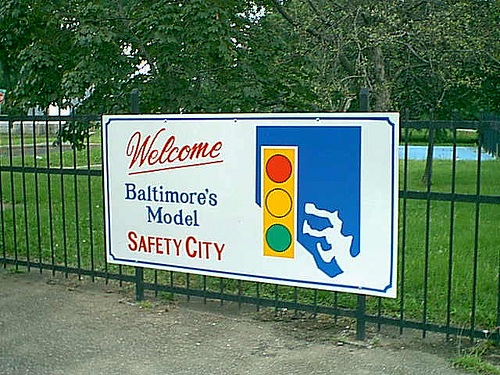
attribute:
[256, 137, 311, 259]
light — traffic, stop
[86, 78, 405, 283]
sign — rectangular, attached, red, safety, city, light, welcome, word, cit, baltimore, circle, white, large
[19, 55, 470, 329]
fence — black, rail, metal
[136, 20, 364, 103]
tree — green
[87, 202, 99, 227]
grass — green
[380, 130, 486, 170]
pond — swimming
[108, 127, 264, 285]
word — safe, welcome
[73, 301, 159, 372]
side walk — grey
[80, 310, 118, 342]
path — asphalt